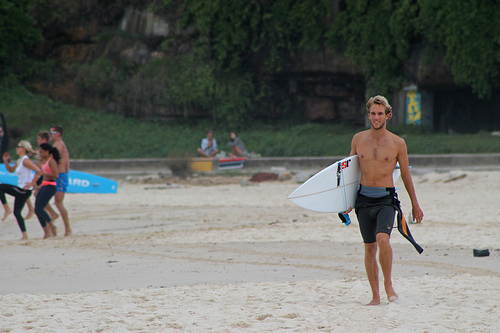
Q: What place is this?
A: It is a beach.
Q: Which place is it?
A: It is a beach.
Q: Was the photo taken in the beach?
A: Yes, it was taken in the beach.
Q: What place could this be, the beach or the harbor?
A: It is the beach.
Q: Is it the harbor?
A: No, it is the beach.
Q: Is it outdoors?
A: Yes, it is outdoors.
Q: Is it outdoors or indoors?
A: It is outdoors.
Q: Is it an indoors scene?
A: No, it is outdoors.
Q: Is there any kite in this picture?
A: No, there are no kites.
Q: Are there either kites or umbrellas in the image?
A: No, there are no kites or umbrellas.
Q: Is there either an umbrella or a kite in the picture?
A: No, there are no kites or umbrellas.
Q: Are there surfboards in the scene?
A: Yes, there is a surfboard.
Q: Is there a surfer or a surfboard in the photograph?
A: Yes, there is a surfboard.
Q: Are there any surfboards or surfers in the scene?
A: Yes, there is a surfboard.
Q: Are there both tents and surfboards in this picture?
A: No, there is a surfboard but no tents.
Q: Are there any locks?
A: No, there are no locks.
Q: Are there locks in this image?
A: No, there are no locks.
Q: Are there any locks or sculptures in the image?
A: No, there are no locks or sculptures.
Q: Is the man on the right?
A: Yes, the man is on the right of the image.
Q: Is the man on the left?
A: No, the man is on the right of the image.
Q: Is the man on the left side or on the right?
A: The man is on the right of the image.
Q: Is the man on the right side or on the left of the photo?
A: The man is on the right of the image.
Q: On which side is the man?
A: The man is on the right of the image.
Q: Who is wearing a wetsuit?
A: The man is wearing a wetsuit.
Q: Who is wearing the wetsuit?
A: The man is wearing a wetsuit.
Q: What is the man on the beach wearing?
A: The man is wearing a wetsuit.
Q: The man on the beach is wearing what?
A: The man is wearing a wetsuit.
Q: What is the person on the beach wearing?
A: The man is wearing a wetsuit.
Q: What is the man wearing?
A: The man is wearing a wetsuit.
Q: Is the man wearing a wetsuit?
A: Yes, the man is wearing a wetsuit.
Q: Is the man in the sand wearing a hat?
A: No, the man is wearing a wetsuit.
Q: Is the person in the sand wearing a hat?
A: No, the man is wearing a wetsuit.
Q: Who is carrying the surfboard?
A: The man is carrying the surfboard.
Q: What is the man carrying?
A: The man is carrying a surfboard.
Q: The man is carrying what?
A: The man is carrying a surfboard.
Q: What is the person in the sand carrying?
A: The man is carrying a surfboard.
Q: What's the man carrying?
A: The man is carrying a surfboard.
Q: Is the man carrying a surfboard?
A: Yes, the man is carrying a surfboard.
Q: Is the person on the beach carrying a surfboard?
A: Yes, the man is carrying a surfboard.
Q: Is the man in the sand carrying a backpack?
A: No, the man is carrying a surfboard.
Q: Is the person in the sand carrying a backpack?
A: No, the man is carrying a surfboard.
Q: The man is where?
A: The man is on the beach.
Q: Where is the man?
A: The man is on the beach.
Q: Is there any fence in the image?
A: No, there are no fences.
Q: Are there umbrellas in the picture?
A: No, there are no umbrellas.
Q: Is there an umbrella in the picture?
A: No, there are no umbrellas.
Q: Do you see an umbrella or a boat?
A: No, there are no umbrellas or boats.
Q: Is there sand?
A: Yes, there is sand.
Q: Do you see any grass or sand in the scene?
A: Yes, there is sand.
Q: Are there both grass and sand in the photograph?
A: Yes, there are both sand and grass.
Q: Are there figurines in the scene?
A: No, there are no figurines.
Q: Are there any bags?
A: No, there are no bags.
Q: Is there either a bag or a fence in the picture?
A: No, there are no bags or fences.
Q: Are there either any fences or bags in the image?
A: No, there are no bags or fences.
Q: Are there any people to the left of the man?
A: Yes, there are people to the left of the man.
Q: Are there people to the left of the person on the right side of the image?
A: Yes, there are people to the left of the man.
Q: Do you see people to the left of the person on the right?
A: Yes, there are people to the left of the man.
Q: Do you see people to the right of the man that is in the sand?
A: No, the people are to the left of the man.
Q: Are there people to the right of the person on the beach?
A: No, the people are to the left of the man.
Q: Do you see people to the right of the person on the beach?
A: No, the people are to the left of the man.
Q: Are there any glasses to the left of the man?
A: No, there are people to the left of the man.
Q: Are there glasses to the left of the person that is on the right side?
A: No, there are people to the left of the man.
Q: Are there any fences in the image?
A: No, there are no fences.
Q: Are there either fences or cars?
A: No, there are no fences or cars.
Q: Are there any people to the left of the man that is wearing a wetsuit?
A: Yes, there are people to the left of the man.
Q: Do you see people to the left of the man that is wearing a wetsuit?
A: Yes, there are people to the left of the man.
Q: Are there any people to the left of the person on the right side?
A: Yes, there are people to the left of the man.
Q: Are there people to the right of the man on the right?
A: No, the people are to the left of the man.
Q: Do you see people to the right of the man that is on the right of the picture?
A: No, the people are to the left of the man.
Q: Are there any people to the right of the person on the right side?
A: No, the people are to the left of the man.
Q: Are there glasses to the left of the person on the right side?
A: No, there are people to the left of the man.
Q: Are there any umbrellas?
A: No, there are no umbrellas.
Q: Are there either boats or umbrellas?
A: No, there are no umbrellas or boats.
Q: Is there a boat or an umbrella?
A: No, there are no umbrellas or boats.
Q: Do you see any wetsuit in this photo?
A: Yes, there is a wetsuit.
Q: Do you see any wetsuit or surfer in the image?
A: Yes, there is a wetsuit.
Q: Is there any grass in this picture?
A: Yes, there is grass.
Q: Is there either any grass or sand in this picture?
A: Yes, there is grass.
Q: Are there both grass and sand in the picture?
A: Yes, there are both grass and sand.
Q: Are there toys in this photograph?
A: No, there are no toys.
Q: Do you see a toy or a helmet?
A: No, there are no toys or helmets.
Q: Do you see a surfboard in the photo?
A: Yes, there is a surfboard.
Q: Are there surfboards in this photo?
A: Yes, there is a surfboard.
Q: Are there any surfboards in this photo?
A: Yes, there is a surfboard.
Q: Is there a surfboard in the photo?
A: Yes, there is a surfboard.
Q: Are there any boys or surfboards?
A: Yes, there is a surfboard.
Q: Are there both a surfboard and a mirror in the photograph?
A: No, there is a surfboard but no mirrors.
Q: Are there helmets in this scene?
A: No, there are no helmets.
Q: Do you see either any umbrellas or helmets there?
A: No, there are no helmets or umbrellas.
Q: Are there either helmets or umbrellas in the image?
A: No, there are no helmets or umbrellas.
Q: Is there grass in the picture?
A: Yes, there is grass.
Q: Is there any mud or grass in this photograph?
A: Yes, there is grass.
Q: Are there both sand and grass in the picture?
A: Yes, there are both grass and sand.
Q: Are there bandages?
A: No, there are no bandages.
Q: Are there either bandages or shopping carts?
A: No, there are no bandages or shopping carts.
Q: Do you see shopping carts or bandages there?
A: No, there are no bandages or shopping carts.